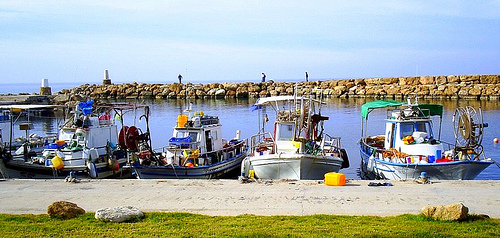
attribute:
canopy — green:
[361, 99, 443, 151]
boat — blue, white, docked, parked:
[360, 98, 494, 180]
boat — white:
[241, 95, 344, 179]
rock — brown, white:
[48, 201, 86, 220]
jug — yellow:
[324, 172, 347, 186]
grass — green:
[0, 214, 498, 237]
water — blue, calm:
[0, 83, 498, 180]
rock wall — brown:
[2, 75, 499, 103]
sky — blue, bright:
[0, 1, 497, 84]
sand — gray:
[0, 176, 499, 217]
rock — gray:
[420, 203, 468, 222]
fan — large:
[453, 105, 489, 161]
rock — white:
[94, 207, 145, 223]